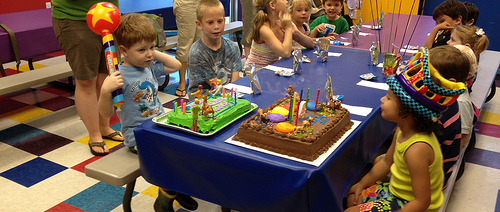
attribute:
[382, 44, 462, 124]
hat — multicolor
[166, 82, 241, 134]
birthday cake — green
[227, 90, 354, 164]
cake — chocolate, large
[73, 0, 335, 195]
party — birthday, child's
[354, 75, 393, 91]
paper — white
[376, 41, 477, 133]
hat — colorful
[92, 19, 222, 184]
child — sitting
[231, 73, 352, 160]
cake — brown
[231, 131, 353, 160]
icing — brown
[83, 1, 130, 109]
toy — red, yellow, dark blue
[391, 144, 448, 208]
shirt — yellow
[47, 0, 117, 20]
shirt — green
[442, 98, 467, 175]
shirt — striped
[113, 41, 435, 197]
table — blue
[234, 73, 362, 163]
cake — chocolate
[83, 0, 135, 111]
toy — large, colorful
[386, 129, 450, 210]
tank — bright, yellow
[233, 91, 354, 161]
brown cake — frosted, birthday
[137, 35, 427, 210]
table cloth — blue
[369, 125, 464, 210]
shirt — yellow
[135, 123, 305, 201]
tablecloth — blue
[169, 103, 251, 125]
icing — green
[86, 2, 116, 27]
design — star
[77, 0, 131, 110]
toy — blow up, wand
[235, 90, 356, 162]
cake — brown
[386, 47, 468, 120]
crown — blown up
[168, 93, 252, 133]
cake — birthday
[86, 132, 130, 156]
sandals — brown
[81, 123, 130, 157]
feet — woman's